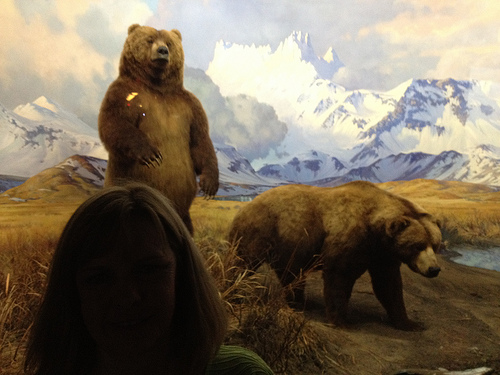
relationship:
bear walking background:
[229, 180, 446, 329] [222, 83, 424, 322]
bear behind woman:
[18, 20, 246, 372] [64, 175, 204, 333]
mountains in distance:
[9, 42, 481, 164] [258, 30, 462, 161]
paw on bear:
[138, 143, 166, 170] [229, 180, 446, 329]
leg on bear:
[319, 267, 362, 329] [229, 180, 446, 329]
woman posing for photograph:
[39, 183, 251, 373] [8, 6, 492, 369]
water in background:
[453, 241, 498, 272] [6, 7, 488, 374]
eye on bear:
[402, 242, 422, 256] [229, 180, 446, 329]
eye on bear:
[145, 35, 154, 44] [97, 21, 221, 237]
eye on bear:
[164, 36, 170, 46] [97, 21, 221, 237]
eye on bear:
[431, 237, 442, 253] [229, 180, 446, 329]